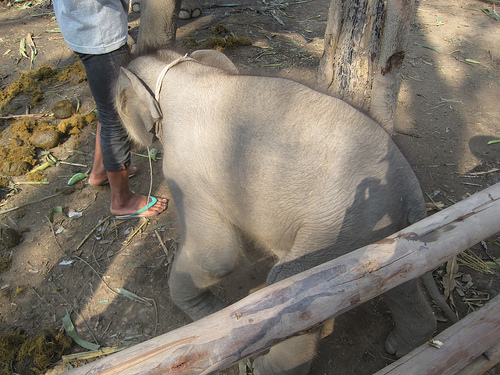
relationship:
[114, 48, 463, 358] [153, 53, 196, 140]
elephant wearing string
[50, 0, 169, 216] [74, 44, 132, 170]
person wearing jeans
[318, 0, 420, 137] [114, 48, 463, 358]
trunk by elephant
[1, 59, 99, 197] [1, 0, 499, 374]
poop on ground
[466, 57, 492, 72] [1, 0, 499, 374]
leaf on ground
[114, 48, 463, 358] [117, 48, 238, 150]
elephant has head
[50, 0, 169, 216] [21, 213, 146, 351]
person has shadow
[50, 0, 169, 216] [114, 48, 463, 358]
person by elephant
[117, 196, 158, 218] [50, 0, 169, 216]
flip flop on person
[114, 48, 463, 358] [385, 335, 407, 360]
elephant has toe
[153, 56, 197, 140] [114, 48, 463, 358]
string on elephant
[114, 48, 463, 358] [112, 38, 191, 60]
elephant has hair